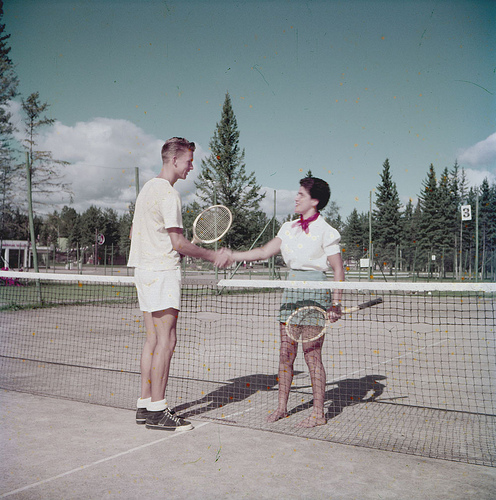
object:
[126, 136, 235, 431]
man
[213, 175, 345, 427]
lady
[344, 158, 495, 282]
pine tree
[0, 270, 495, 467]
tennis net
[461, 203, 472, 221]
sign